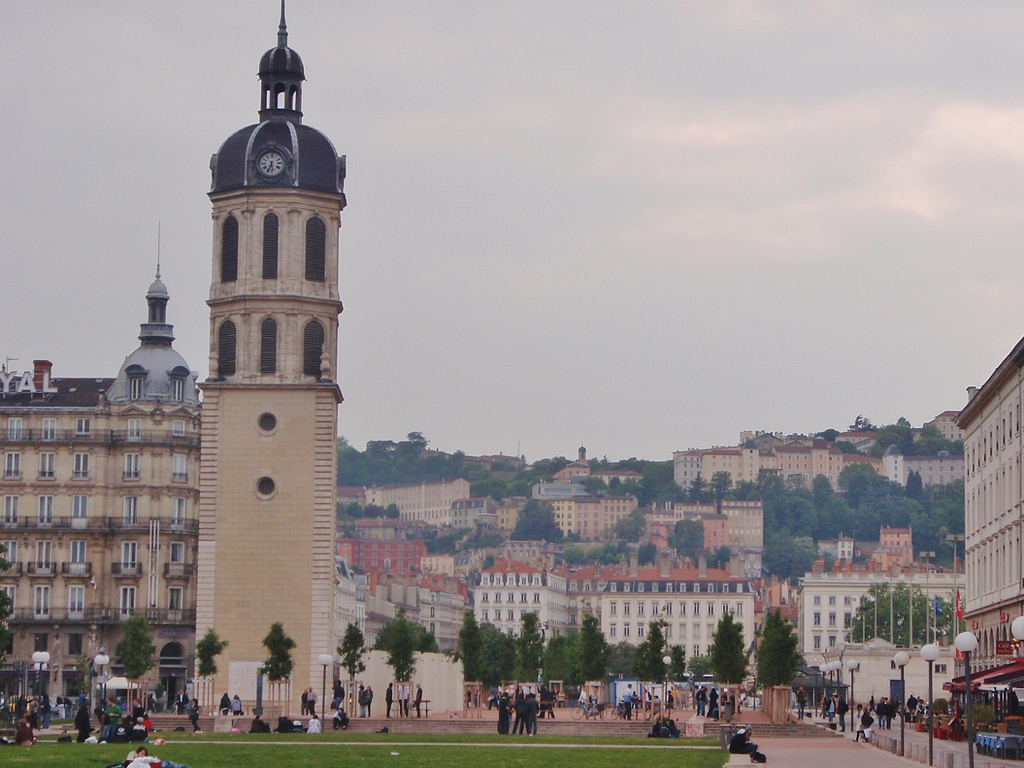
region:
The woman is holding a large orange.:
[563, 687, 587, 727]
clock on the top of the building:
[200, 121, 303, 191]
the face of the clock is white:
[232, 122, 296, 199]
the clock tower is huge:
[181, 2, 375, 762]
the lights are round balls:
[817, 605, 986, 673]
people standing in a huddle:
[438, 672, 569, 740]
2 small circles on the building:
[226, 374, 290, 529]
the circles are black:
[217, 374, 328, 536]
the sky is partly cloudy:
[434, 58, 928, 376]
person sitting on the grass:
[86, 719, 184, 764]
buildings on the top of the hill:
[516, 396, 944, 507]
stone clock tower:
[196, 0, 345, 727]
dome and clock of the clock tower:
[207, 0, 345, 203]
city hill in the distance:
[330, 414, 961, 645]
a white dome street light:
[920, 641, 943, 763]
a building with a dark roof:
[601, 576, 763, 674]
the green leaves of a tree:
[261, 619, 294, 683]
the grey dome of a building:
[106, 215, 202, 408]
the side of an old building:
[947, 335, 1021, 661]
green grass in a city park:
[1, 732, 733, 765]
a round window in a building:
[256, 473, 279, 500]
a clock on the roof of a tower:
[261, 148, 287, 180]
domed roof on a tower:
[208, 121, 346, 201]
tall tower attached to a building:
[189, 2, 348, 723]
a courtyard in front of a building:
[0, 719, 737, 765]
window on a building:
[122, 543, 139, 573]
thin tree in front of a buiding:
[341, 631, 370, 720]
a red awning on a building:
[947, 662, 1021, 700]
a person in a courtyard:
[523, 698, 543, 738]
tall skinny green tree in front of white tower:
[261, 618, 293, 723]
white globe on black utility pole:
[918, 641, 942, 660]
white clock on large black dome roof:
[250, 148, 288, 177]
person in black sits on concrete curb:
[731, 729, 764, 759]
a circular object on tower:
[257, 50, 303, 79]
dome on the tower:
[213, 126, 341, 191]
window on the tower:
[220, 214, 241, 278]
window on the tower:
[258, 217, 279, 276]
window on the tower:
[305, 214, 325, 284]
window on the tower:
[213, 322, 236, 379]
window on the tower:
[258, 318, 282, 372]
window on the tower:
[304, 321, 321, 379]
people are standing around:
[492, 694, 540, 740]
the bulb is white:
[955, 633, 976, 654]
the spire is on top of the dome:
[267, 9, 294, 70]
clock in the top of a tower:
[261, 148, 285, 186]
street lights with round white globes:
[842, 615, 1023, 767]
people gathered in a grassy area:
[11, 666, 761, 765]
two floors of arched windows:
[209, 204, 345, 379]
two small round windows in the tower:
[252, 409, 281, 502]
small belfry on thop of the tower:
[261, 6, 306, 118]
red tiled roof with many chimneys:
[484, 552, 759, 598]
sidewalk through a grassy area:
[162, 726, 731, 766]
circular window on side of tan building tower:
[247, 469, 279, 504]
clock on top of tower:
[250, 143, 295, 183]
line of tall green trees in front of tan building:
[101, 602, 809, 732]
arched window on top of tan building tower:
[253, 308, 283, 381]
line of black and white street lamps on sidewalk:
[819, 611, 1022, 767]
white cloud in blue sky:
[616, 75, 1018, 268]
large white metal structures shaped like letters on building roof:
[3, 362, 68, 407]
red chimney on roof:
[21, 355, 59, 393]